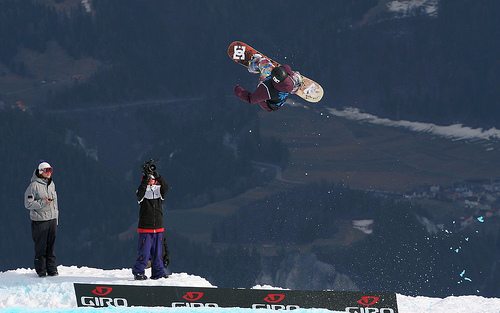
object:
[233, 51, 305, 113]
man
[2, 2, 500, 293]
air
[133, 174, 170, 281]
man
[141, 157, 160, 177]
camera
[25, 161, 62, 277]
man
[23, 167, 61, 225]
coat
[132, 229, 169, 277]
pants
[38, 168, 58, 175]
goggles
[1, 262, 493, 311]
snow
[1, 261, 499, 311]
ground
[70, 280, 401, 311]
banner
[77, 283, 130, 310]
giro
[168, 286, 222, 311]
giro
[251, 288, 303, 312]
giro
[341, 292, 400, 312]
giro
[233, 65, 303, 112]
jacket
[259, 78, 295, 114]
vest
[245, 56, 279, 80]
pants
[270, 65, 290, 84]
helmet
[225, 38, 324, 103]
snowboard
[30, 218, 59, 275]
pants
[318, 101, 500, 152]
snow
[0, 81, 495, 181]
hill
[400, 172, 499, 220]
town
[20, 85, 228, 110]
road